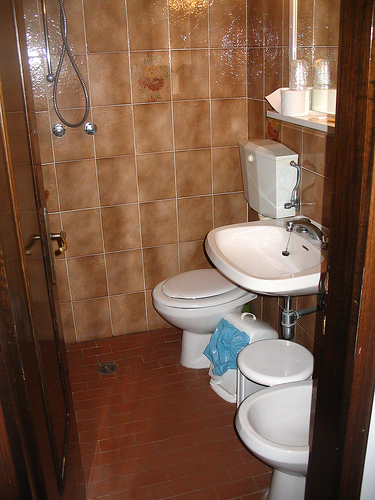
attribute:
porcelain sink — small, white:
[202, 211, 323, 295]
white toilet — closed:
[149, 265, 262, 375]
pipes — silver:
[281, 298, 301, 334]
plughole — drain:
[98, 360, 117, 376]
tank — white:
[236, 141, 298, 212]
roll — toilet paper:
[267, 84, 309, 117]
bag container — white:
[201, 318, 242, 374]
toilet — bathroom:
[233, 378, 314, 498]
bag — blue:
[202, 316, 248, 377]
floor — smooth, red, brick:
[60, 326, 279, 499]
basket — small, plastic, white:
[205, 308, 281, 407]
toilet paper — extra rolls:
[275, 80, 307, 115]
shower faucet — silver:
[37, 1, 98, 139]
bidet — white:
[228, 376, 320, 498]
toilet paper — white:
[262, 85, 307, 117]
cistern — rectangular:
[237, 136, 301, 218]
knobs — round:
[49, 121, 98, 140]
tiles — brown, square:
[75, 167, 143, 249]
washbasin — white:
[200, 215, 323, 302]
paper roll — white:
[272, 84, 313, 115]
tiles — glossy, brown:
[24, 2, 247, 224]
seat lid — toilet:
[161, 256, 227, 306]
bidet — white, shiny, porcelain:
[231, 378, 313, 498]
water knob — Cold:
[85, 108, 117, 157]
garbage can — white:
[208, 310, 279, 398]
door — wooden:
[8, 124, 32, 425]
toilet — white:
[155, 268, 227, 360]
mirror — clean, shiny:
[294, 0, 336, 114]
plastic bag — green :
[202, 319, 250, 378]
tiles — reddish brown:
[87, 373, 180, 452]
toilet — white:
[165, 146, 281, 377]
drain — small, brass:
[92, 358, 124, 378]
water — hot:
[51, 121, 76, 140]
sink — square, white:
[200, 209, 324, 314]